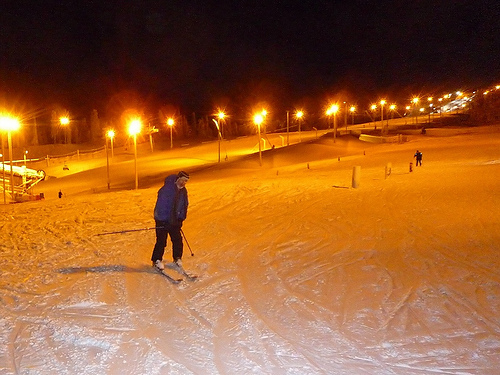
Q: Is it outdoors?
A: Yes, it is outdoors.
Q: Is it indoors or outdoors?
A: It is outdoors.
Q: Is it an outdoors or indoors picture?
A: It is outdoors.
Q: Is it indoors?
A: No, it is outdoors.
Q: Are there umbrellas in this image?
A: No, there are no umbrellas.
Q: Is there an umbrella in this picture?
A: No, there are no umbrellas.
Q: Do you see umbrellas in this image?
A: No, there are no umbrellas.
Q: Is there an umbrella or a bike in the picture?
A: No, there are no umbrellas or bikes.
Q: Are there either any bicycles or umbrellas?
A: No, there are no umbrellas or bicycles.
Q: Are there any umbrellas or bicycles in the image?
A: No, there are no umbrellas or bicycles.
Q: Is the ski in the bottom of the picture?
A: Yes, the ski is in the bottom of the image.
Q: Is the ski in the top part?
A: No, the ski is in the bottom of the image.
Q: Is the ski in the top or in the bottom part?
A: The ski is in the bottom of the image.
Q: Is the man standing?
A: Yes, the man is standing.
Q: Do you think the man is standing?
A: Yes, the man is standing.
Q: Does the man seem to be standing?
A: Yes, the man is standing.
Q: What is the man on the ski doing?
A: The man is standing.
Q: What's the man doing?
A: The man is standing.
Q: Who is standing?
A: The man is standing.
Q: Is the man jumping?
A: No, the man is standing.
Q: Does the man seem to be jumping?
A: No, the man is standing.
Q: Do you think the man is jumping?
A: No, the man is standing.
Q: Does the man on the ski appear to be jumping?
A: No, the man is standing.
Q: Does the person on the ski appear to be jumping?
A: No, the man is standing.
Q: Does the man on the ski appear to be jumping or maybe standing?
A: The man is standing.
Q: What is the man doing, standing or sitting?
A: The man is standing.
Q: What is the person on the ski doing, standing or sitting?
A: The man is standing.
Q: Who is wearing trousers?
A: The man is wearing trousers.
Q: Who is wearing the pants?
A: The man is wearing trousers.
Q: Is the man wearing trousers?
A: Yes, the man is wearing trousers.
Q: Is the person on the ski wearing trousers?
A: Yes, the man is wearing trousers.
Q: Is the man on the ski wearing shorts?
A: No, the man is wearing trousers.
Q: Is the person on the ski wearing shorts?
A: No, the man is wearing trousers.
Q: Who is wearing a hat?
A: The man is wearing a hat.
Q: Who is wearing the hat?
A: The man is wearing a hat.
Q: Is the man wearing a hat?
A: Yes, the man is wearing a hat.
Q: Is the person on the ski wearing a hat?
A: Yes, the man is wearing a hat.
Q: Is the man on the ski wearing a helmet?
A: No, the man is wearing a hat.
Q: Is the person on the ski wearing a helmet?
A: No, the man is wearing a hat.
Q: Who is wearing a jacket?
A: The man is wearing a jacket.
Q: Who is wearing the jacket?
A: The man is wearing a jacket.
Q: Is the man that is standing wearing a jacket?
A: Yes, the man is wearing a jacket.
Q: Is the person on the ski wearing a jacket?
A: Yes, the man is wearing a jacket.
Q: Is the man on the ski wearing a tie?
A: No, the man is wearing a jacket.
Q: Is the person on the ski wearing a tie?
A: No, the man is wearing a jacket.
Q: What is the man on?
A: The man is on the ski.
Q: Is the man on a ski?
A: Yes, the man is on a ski.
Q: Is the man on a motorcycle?
A: No, the man is on a ski.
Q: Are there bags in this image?
A: No, there are no bags.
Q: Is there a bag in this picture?
A: No, there are no bags.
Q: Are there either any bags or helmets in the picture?
A: No, there are no bags or helmets.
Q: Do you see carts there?
A: No, there are no carts.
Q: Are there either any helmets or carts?
A: No, there are no carts or helmets.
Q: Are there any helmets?
A: No, there are no helmets.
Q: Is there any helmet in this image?
A: No, there are no helmets.